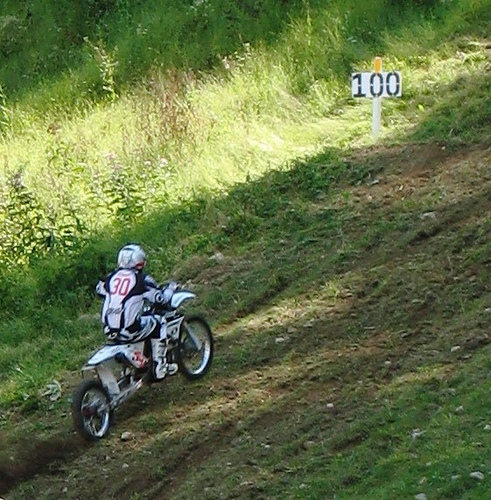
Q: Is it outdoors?
A: Yes, it is outdoors.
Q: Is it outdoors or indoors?
A: It is outdoors.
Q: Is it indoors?
A: No, it is outdoors.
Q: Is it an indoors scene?
A: No, it is outdoors.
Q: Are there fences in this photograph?
A: No, there are no fences.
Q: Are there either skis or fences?
A: No, there are no fences or skis.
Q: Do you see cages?
A: No, there are no cages.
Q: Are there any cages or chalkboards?
A: No, there are no cages or chalkboards.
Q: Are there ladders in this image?
A: No, there are no ladders.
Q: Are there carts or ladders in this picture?
A: No, there are no ladders or carts.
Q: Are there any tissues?
A: No, there are no tissues.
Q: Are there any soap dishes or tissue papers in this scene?
A: No, there are no tissue papers or soap dishes.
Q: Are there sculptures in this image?
A: No, there are no sculptures.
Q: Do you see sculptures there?
A: No, there are no sculptures.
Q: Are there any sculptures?
A: No, there are no sculptures.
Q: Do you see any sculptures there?
A: No, there are no sculptures.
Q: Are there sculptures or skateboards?
A: No, there are no sculptures or skateboards.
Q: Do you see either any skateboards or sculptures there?
A: No, there are no sculptures or skateboards.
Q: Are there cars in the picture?
A: No, there are no cars.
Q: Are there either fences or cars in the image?
A: No, there are no cars or fences.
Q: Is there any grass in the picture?
A: Yes, there is grass.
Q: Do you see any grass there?
A: Yes, there is grass.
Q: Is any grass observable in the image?
A: Yes, there is grass.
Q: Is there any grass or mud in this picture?
A: Yes, there is grass.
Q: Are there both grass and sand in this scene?
A: No, there is grass but no sand.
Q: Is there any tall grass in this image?
A: Yes, there is tall grass.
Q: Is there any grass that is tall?
A: Yes, there is grass that is tall.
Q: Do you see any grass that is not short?
A: Yes, there is tall grass.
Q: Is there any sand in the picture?
A: No, there is no sand.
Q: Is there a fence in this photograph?
A: No, there are no fences.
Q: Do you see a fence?
A: No, there are no fences.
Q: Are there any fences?
A: No, there are no fences.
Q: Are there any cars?
A: No, there are no cars.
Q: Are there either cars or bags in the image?
A: No, there are no cars or bags.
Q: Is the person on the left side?
A: Yes, the person is on the left of the image.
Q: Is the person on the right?
A: No, the person is on the left of the image.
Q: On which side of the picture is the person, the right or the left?
A: The person is on the left of the image.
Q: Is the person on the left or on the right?
A: The person is on the left of the image.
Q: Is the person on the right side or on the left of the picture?
A: The person is on the left of the image.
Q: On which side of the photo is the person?
A: The person is on the left of the image.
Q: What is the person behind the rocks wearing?
A: The person is wearing an outfit.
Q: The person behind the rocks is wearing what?
A: The person is wearing an outfit.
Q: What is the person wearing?
A: The person is wearing an outfit.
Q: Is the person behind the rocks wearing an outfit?
A: Yes, the person is wearing an outfit.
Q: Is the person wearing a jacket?
A: No, the person is wearing an outfit.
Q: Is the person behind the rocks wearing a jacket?
A: No, the person is wearing an outfit.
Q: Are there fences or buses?
A: No, there are no fences or buses.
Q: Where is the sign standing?
A: The sign is standing in the field.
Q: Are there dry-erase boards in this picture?
A: No, there are no dry-erase boards.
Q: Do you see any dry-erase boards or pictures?
A: No, there are no dry-erase boards or pictures.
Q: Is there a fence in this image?
A: No, there are no fences.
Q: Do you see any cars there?
A: No, there are no cars.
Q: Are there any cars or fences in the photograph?
A: No, there are no cars or fences.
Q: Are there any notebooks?
A: No, there are no notebooks.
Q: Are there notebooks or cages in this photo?
A: No, there are no notebooks or cages.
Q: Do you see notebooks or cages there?
A: No, there are no notebooks or cages.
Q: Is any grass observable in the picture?
A: Yes, there is grass.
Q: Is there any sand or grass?
A: Yes, there is grass.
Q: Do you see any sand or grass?
A: Yes, there is grass.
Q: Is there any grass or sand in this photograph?
A: Yes, there is grass.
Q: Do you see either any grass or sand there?
A: Yes, there is grass.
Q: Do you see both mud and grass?
A: No, there is grass but no mud.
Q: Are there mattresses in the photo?
A: No, there are no mattresses.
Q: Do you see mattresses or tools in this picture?
A: No, there are no mattresses or tools.